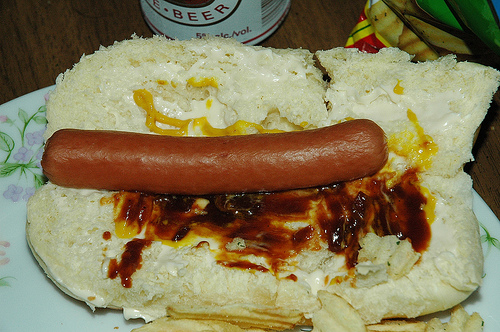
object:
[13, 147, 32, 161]
flower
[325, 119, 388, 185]
section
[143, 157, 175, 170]
smokie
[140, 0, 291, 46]
can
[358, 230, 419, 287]
chip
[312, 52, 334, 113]
tear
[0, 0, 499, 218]
table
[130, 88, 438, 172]
mustard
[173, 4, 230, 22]
beer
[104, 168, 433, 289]
sauce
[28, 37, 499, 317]
bun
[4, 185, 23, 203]
flowers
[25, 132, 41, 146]
flowers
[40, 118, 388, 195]
hot dog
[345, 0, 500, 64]
bag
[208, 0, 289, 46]
part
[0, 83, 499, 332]
plate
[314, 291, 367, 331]
chips